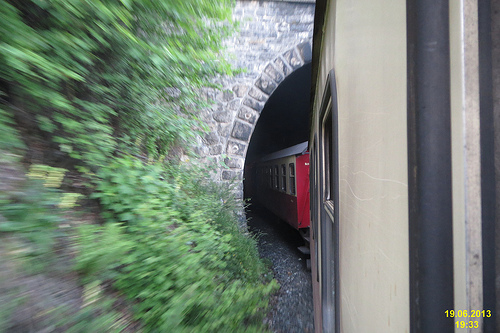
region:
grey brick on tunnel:
[221, 169, 243, 179]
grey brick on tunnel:
[222, 153, 244, 169]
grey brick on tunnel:
[222, 139, 247, 155]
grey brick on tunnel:
[230, 118, 251, 143]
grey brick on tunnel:
[237, 105, 256, 122]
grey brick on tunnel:
[241, 93, 262, 111]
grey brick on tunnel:
[246, 84, 264, 101]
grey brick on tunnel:
[253, 73, 275, 93]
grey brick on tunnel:
[266, 65, 282, 83]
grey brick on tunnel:
[297, 42, 312, 62]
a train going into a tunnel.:
[201, 0, 498, 332]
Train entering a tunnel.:
[257, 7, 490, 327]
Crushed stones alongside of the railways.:
[255, 212, 315, 328]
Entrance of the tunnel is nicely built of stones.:
[197, 11, 310, 281]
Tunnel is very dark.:
[246, 68, 307, 258]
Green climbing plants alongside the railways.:
[5, 21, 226, 326]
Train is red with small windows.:
[263, 138, 311, 258]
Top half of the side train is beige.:
[312, 3, 412, 328]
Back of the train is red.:
[295, 152, 310, 248]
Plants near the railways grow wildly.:
[3, 5, 243, 316]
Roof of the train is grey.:
[255, 137, 311, 163]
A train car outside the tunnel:
[309, 0, 499, 330]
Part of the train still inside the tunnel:
[252, 141, 309, 266]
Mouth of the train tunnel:
[224, 40, 313, 293]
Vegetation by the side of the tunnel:
[0, 3, 277, 332]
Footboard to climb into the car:
[297, 228, 311, 268]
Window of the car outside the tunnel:
[319, 68, 338, 222]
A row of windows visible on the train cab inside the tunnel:
[258, 162, 295, 198]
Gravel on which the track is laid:
[249, 213, 313, 331]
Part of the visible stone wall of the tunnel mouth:
[174, 0, 313, 237]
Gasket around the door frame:
[405, 3, 453, 330]